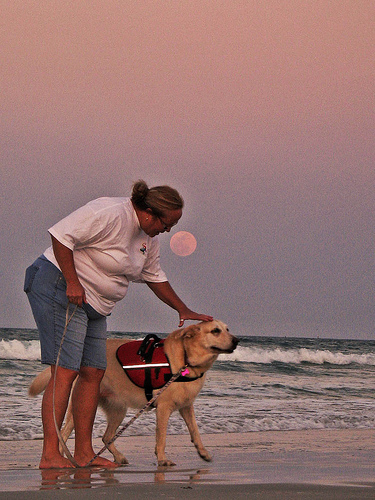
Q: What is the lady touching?
A: A dog.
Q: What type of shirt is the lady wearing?
A: A short sleeved shirt.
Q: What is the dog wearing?
A: A vest.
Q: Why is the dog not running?
A: Leashed.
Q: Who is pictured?
A: A woman and a dog.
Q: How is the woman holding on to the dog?
A: With a leash.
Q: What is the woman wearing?
A: A t-shirt and shorts.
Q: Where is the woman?
A: On a beach.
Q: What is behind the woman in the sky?
A: The Moon.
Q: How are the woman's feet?
A: Bare.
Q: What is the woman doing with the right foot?
A: Stepping on the leash.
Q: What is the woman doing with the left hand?
A: Petting the dog.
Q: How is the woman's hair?
A: Tied in a bun.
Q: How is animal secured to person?
A: Leash.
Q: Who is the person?
A: Woman.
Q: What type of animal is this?
A: Dog.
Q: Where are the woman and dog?
A: Beach.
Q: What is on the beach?
A: Sand.